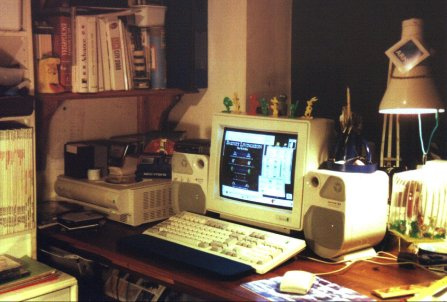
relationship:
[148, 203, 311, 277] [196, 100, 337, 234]
keyboard front monitor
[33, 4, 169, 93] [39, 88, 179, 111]
white book on shelf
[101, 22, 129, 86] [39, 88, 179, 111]
white book on shelf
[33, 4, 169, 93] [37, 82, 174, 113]
white book on shelf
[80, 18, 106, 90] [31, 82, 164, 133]
book on shelf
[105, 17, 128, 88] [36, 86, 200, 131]
book on shelf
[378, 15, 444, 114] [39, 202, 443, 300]
lamp on table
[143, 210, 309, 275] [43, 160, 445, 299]
keyboard on desk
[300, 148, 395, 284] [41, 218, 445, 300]
speaker on desk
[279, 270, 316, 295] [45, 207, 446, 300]
mouse on desk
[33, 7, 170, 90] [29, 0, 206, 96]
books on a shelf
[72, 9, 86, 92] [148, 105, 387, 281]
book near a computer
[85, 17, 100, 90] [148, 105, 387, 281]
book near a computer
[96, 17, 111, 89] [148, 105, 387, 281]
book near a computer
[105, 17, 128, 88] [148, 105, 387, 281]
book near a computer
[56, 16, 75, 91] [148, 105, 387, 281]
book near a computer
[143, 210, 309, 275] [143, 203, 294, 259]
keyboard on keyboard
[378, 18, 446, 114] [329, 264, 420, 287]
lamp on desk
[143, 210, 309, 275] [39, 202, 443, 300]
keyboard on table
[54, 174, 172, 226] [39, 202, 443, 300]
fax machine on table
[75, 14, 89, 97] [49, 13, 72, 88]
book next to book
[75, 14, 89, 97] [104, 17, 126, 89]
book next to book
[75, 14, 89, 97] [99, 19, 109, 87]
book next to book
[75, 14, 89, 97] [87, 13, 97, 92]
book next to book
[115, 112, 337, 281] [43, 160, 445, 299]
computer on desk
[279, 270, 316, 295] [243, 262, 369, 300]
mouse on mouse pad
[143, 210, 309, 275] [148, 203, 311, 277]
keyboard on keyboard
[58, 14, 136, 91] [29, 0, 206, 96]
books on shelf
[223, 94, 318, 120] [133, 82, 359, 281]
figurine on top of computer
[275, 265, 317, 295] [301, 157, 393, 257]
mouse sitting in front of cpu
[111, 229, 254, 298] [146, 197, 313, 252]
cushion sitting in front of keyboard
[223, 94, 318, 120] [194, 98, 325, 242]
figurine standing on top of monitor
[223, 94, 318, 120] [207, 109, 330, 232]
figurine standing on top of computer monitor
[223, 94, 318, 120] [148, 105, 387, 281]
figurine standing on top of computer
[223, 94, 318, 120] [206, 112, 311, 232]
figurine standing on top of computer monitor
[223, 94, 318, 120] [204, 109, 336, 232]
figurine standing on top of monitor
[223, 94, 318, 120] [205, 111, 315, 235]
figurine standing on top of computer monitor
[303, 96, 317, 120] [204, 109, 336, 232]
figurine standing on top of monitor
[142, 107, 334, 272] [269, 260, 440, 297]
computer on desk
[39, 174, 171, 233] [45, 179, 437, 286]
fax machine on desk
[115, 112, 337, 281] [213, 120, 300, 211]
computer has screen